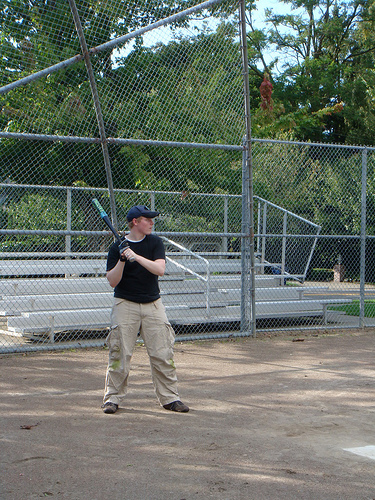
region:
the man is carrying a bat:
[87, 198, 177, 307]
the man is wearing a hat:
[125, 197, 180, 243]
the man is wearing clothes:
[88, 186, 200, 449]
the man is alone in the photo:
[7, 129, 370, 495]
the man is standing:
[92, 189, 205, 438]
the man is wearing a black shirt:
[98, 226, 187, 311]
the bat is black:
[80, 190, 136, 316]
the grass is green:
[338, 300, 373, 321]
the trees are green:
[20, 28, 365, 201]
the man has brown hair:
[125, 212, 153, 235]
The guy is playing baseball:
[86, 198, 196, 425]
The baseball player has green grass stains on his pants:
[106, 343, 179, 377]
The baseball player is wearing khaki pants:
[98, 290, 182, 404]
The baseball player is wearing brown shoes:
[96, 397, 194, 413]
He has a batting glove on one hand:
[114, 237, 133, 261]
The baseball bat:
[80, 195, 134, 259]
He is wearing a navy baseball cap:
[124, 201, 159, 221]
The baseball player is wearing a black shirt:
[100, 229, 172, 307]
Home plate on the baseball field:
[336, 421, 374, 487]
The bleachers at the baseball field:
[0, 180, 363, 341]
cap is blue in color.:
[124, 202, 165, 226]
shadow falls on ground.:
[58, 383, 316, 464]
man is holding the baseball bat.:
[89, 188, 136, 264]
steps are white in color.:
[20, 262, 86, 342]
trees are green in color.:
[281, 61, 335, 112]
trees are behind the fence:
[276, 90, 360, 182]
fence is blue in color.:
[264, 80, 354, 186]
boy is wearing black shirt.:
[100, 230, 179, 303]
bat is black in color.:
[94, 193, 132, 263]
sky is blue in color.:
[256, 13, 307, 59]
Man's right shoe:
[99, 401, 118, 414]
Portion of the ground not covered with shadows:
[192, 349, 232, 373]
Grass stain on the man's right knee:
[106, 353, 126, 373]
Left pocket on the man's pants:
[150, 299, 163, 312]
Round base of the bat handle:
[126, 253, 143, 264]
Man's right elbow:
[105, 274, 120, 290]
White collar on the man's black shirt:
[124, 234, 151, 244]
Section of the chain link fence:
[264, 153, 354, 198]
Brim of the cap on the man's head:
[139, 207, 162, 220]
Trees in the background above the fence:
[292, 6, 354, 128]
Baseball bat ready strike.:
[89, 192, 131, 262]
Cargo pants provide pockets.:
[99, 296, 180, 399]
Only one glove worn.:
[109, 234, 142, 288]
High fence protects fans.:
[183, 4, 264, 336]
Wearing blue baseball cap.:
[121, 203, 164, 231]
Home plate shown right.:
[265, 397, 374, 475]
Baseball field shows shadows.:
[227, 347, 337, 462]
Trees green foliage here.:
[270, 143, 368, 291]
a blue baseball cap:
[123, 203, 161, 221]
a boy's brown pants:
[101, 295, 180, 405]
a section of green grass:
[333, 298, 371, 318]